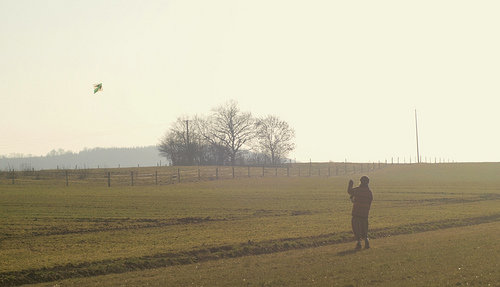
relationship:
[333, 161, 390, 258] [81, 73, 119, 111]
man flying kite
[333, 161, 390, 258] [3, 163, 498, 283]
man in field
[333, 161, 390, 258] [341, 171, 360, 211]
man has arm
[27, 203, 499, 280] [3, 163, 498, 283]
drench in field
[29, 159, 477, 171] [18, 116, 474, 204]
gate in background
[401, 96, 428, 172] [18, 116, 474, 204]
pole in background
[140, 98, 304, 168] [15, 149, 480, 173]
tree behind fence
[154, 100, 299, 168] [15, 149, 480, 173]
tree behind fence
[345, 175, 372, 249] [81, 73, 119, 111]
man flying kite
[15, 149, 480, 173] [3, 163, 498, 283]
fence in field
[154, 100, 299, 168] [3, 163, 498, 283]
tree in field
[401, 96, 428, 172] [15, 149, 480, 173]
pole on fence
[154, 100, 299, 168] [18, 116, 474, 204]
tree in background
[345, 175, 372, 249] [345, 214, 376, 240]
man has shorts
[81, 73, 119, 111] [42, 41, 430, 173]
kite in air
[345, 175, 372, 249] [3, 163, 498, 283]
man in field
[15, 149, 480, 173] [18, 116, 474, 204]
fence in background